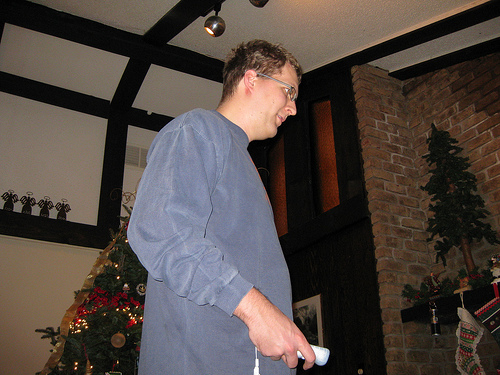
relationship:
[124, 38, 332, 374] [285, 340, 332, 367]
person holding remote control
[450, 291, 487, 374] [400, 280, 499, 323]
stocking hanging from mantel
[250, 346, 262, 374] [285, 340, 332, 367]
tassel hanging from remote control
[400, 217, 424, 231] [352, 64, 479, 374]
brick mounted on wall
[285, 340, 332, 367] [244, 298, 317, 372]
remote control held in hand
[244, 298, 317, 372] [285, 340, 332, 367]
hand holding remote control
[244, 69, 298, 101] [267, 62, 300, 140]
glasses worn on face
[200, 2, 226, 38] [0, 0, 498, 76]
light hanging on ceiling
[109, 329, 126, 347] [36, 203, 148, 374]
ornament hanging on tree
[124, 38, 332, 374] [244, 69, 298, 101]
person wearing glasses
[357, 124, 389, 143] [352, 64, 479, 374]
brick mounted on wall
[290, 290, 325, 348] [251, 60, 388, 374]
picture hanging on wall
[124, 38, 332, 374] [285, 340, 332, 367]
person using remote control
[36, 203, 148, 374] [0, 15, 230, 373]
tree standing in background